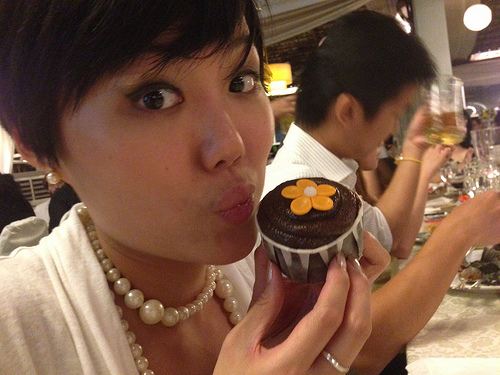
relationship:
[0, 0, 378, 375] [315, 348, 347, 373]
people wearing ring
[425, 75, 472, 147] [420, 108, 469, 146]
glass with mug beer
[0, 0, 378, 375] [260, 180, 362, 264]
people holding cupcake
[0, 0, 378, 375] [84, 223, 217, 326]
people wearing pearl necklaces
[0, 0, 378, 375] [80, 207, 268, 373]
people wearing necklace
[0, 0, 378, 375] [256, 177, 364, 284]
people holding cupcake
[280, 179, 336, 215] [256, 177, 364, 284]
flower on cupcake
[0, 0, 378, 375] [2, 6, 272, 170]
people with hair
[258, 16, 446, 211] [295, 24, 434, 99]
man with brown hair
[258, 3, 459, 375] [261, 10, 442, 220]
man wearing shirt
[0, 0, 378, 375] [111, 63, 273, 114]
people with eyes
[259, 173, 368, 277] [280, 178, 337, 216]
cake with flower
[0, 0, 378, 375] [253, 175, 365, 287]
people holding cake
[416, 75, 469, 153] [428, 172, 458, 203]
mug beer of beer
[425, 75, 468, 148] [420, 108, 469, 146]
glass raising mug beer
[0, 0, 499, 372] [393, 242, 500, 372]
people at table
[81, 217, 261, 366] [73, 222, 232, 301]
necklace around neck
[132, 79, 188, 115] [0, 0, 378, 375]
eye of people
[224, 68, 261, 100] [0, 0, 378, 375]
eye of people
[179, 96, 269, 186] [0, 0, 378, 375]
nose of people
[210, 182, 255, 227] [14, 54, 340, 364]
lips of woman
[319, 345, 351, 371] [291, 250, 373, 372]
ring on finger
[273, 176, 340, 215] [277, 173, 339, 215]
frosting on flower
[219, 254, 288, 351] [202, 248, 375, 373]
thumb of hand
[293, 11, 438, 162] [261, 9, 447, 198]
head of man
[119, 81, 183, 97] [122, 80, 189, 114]
eye shadow above eye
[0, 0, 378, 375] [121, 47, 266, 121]
people has eyes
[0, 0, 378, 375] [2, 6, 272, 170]
people has hair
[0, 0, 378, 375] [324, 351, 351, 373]
people wearing ring